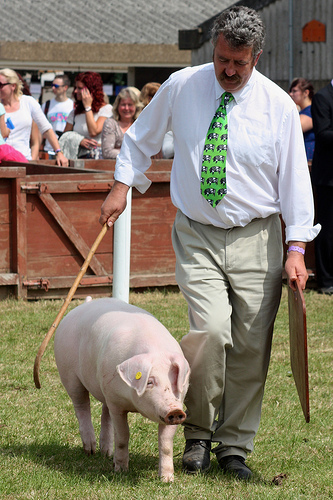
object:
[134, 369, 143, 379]
tag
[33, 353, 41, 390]
crook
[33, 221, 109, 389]
stick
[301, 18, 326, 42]
object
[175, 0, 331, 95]
building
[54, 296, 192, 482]
pig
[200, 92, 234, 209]
green tie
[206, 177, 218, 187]
pig design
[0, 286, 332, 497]
ground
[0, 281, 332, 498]
grass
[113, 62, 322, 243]
shirt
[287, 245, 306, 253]
wristband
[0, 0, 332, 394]
photo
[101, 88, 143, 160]
person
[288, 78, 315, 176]
person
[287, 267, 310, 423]
brown board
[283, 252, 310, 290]
right hand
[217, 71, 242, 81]
mustache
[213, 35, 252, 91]
face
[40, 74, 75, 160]
man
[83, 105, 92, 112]
watch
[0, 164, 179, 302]
fence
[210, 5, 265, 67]
hair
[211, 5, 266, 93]
head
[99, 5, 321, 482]
man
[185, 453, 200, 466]
dirt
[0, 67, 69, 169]
person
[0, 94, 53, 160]
shirt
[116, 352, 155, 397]
ears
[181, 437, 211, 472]
shoe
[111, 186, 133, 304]
pole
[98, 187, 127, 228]
hand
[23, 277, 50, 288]
bolt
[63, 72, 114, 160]
lady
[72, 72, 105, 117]
hair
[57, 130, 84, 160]
sweater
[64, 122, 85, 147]
arm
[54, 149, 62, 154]
watch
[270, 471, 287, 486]
lump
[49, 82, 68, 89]
shades